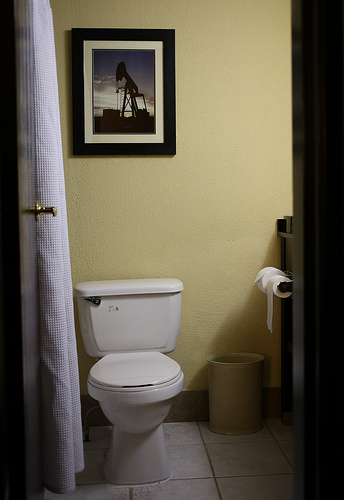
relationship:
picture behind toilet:
[58, 23, 186, 158] [77, 265, 193, 440]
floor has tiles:
[196, 448, 256, 478] [213, 434, 273, 489]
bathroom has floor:
[12, 11, 344, 499] [196, 448, 256, 478]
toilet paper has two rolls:
[269, 276, 292, 302] [248, 260, 299, 339]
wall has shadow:
[213, 54, 254, 117] [215, 313, 270, 345]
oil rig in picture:
[112, 56, 150, 130] [58, 23, 186, 158]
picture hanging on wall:
[58, 23, 186, 158] [213, 54, 254, 117]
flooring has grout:
[179, 433, 200, 451] [189, 454, 213, 479]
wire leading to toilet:
[83, 402, 103, 441] [77, 265, 193, 440]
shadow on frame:
[215, 313, 270, 345] [78, 29, 169, 44]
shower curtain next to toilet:
[33, 21, 62, 168] [77, 265, 193, 440]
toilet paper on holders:
[269, 276, 292, 302] [282, 275, 291, 295]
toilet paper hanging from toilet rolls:
[269, 276, 292, 302] [252, 265, 282, 294]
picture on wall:
[58, 23, 186, 158] [213, 54, 254, 117]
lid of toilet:
[90, 348, 179, 388] [77, 265, 193, 440]